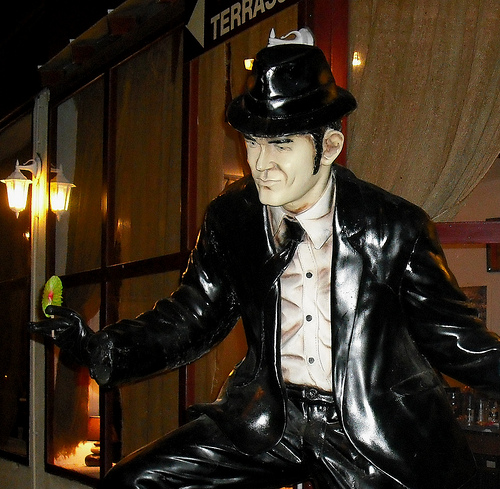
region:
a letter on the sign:
[196, 5, 223, 47]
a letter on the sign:
[225, 6, 244, 34]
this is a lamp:
[48, 163, 74, 222]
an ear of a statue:
[310, 131, 352, 177]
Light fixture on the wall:
[1, 154, 48, 220]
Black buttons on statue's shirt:
[301, 268, 317, 363]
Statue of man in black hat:
[22, 42, 497, 487]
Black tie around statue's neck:
[232, 215, 304, 392]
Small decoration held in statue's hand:
[37, 274, 65, 336]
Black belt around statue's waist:
[283, 381, 334, 404]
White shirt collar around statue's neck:
[260, 163, 335, 248]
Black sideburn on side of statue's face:
[308, 130, 325, 175]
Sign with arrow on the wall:
[180, 2, 300, 59]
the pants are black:
[186, 418, 355, 486]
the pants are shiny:
[184, 411, 354, 477]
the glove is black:
[41, 309, 96, 386]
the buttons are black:
[299, 264, 318, 376]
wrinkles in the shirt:
[277, 274, 299, 386]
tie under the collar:
[272, 210, 326, 253]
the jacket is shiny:
[340, 221, 426, 461]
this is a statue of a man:
[25, 60, 495, 482]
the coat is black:
[155, 205, 446, 447]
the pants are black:
[158, 422, 366, 485]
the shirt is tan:
[260, 206, 353, 399]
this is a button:
[305, 356, 320, 370]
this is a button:
[302, 310, 317, 327]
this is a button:
[303, 263, 320, 285]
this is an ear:
[319, 128, 356, 174]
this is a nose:
[251, 152, 284, 192]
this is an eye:
[262, 125, 308, 164]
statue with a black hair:
[213, 28, 365, 140]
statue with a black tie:
[218, 217, 303, 399]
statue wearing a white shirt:
[251, 209, 356, 409]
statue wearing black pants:
[147, 395, 331, 470]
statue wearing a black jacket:
[118, 201, 258, 368]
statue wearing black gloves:
[27, 302, 109, 372]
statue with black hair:
[304, 123, 324, 182]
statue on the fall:
[1, 145, 53, 219]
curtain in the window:
[103, 57, 181, 249]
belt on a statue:
[282, 378, 349, 406]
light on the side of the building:
[0, 158, 40, 220]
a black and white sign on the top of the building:
[184, 0, 295, 60]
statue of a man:
[30, 45, 498, 484]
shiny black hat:
[224, 45, 358, 134]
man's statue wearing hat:
[21, 35, 496, 487]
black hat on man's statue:
[220, 39, 367, 139]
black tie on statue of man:
[245, 209, 315, 297]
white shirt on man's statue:
[248, 172, 360, 393]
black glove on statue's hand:
[22, 298, 98, 377]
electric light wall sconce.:
[2, 152, 41, 221]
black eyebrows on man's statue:
[238, 133, 295, 147]